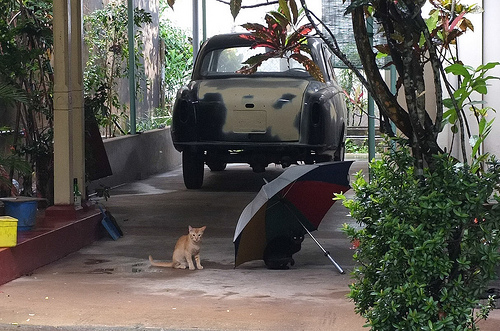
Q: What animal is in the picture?
A: A cat.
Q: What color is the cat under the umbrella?
A: Black.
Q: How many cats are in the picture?
A: Two.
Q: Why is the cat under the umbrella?
A: He's hiding.